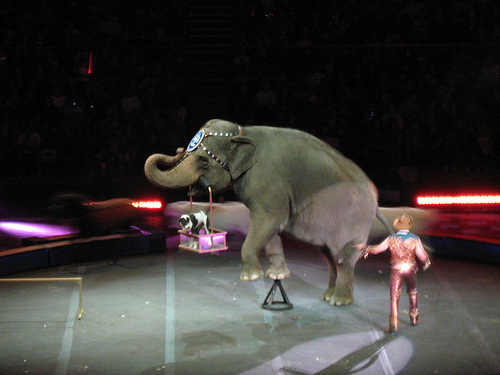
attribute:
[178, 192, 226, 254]
assortment — hanging, pink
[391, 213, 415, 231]
hat — broad-brimmed